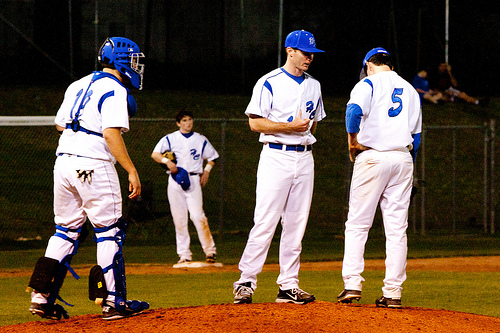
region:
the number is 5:
[378, 79, 411, 129]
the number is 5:
[375, 73, 417, 136]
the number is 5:
[377, 71, 429, 148]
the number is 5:
[368, 68, 426, 145]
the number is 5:
[371, 68, 411, 133]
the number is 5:
[372, 68, 418, 145]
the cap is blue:
[282, 22, 327, 82]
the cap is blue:
[274, 23, 332, 77]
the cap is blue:
[283, 25, 328, 75]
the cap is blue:
[274, 20, 323, 71]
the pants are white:
[243, 157, 319, 299]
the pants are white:
[231, 150, 311, 284]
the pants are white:
[230, 146, 314, 297]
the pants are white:
[237, 143, 314, 285]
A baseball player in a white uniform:
[155, 113, 229, 276]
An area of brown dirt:
[191, 310, 273, 325]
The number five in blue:
[382, 88, 409, 122]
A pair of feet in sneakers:
[232, 279, 331, 316]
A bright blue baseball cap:
[284, 28, 326, 56]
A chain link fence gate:
[427, 125, 497, 243]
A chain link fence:
[5, 112, 53, 211]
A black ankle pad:
[79, 262, 116, 315]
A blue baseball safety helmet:
[98, 37, 150, 91]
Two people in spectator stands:
[410, 63, 484, 109]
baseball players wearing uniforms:
[22, 20, 428, 320]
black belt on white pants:
[258, 131, 315, 158]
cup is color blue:
[277, 21, 325, 63]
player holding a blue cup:
[146, 101, 230, 272]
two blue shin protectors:
[28, 238, 135, 308]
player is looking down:
[330, 33, 425, 319]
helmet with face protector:
[68, 27, 163, 120]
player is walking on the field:
[16, 24, 156, 331]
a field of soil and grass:
[6, 234, 497, 328]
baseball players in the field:
[27, 31, 420, 313]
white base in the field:
[173, 256, 223, 271]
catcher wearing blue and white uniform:
[24, 37, 146, 317]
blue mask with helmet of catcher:
[98, 36, 144, 93]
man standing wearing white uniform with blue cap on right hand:
[153, 113, 221, 265]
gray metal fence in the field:
[0, 117, 499, 262]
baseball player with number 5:
[343, 46, 422, 308]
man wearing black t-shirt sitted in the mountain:
[433, 59, 488, 106]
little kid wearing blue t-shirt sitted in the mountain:
[407, 66, 450, 104]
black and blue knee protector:
[38, 216, 123, 306]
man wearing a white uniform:
[26, 34, 151, 321]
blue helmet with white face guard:
[95, 34, 145, 94]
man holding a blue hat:
[149, 110, 221, 264]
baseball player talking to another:
[233, 27, 425, 308]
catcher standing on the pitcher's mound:
[26, 32, 158, 314]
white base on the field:
[173, 254, 222, 274]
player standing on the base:
[160, 105, 232, 257]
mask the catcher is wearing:
[99, 35, 148, 83]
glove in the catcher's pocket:
[74, 163, 91, 184]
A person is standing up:
[234, 25, 316, 317]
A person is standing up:
[341, 46, 401, 331]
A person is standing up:
[156, 110, 236, 297]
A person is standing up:
[26, 23, 153, 328]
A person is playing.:
[229, 21, 314, 321]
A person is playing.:
[334, 28, 424, 317]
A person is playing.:
[27, 30, 152, 320]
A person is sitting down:
[408, 60, 430, 117]